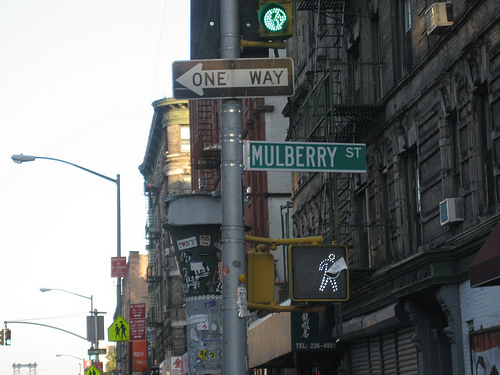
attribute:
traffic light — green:
[253, 6, 305, 53]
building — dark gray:
[317, 20, 485, 285]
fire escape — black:
[312, 30, 385, 257]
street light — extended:
[9, 149, 37, 164]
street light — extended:
[39, 285, 53, 292]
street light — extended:
[53, 351, 62, 358]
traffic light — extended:
[4, 326, 13, 348]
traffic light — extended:
[0, 327, 7, 344]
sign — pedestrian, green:
[106, 317, 131, 341]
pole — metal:
[223, 110, 252, 374]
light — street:
[11, 151, 35, 164]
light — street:
[37, 285, 49, 294]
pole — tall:
[117, 176, 121, 373]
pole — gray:
[216, 162, 248, 270]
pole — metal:
[221, 2, 249, 374]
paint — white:
[433, 287, 495, 362]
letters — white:
[250, 143, 362, 167]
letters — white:
[188, 69, 284, 86]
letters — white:
[131, 346, 148, 362]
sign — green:
[170, 55, 295, 98]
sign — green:
[126, 299, 146, 337]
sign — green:
[109, 255, 126, 278]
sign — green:
[105, 313, 130, 341]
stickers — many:
[173, 236, 198, 251]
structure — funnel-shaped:
[164, 188, 223, 373]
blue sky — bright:
[1, 0, 190, 90]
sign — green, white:
[242, 140, 367, 175]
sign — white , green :
[240, 134, 377, 182]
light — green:
[6, 338, 12, 343]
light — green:
[263, 5, 287, 30]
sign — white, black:
[163, 59, 295, 99]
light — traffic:
[0, 327, 19, 348]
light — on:
[293, 244, 351, 302]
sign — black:
[220, 0, 247, 373]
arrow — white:
[174, 62, 292, 97]